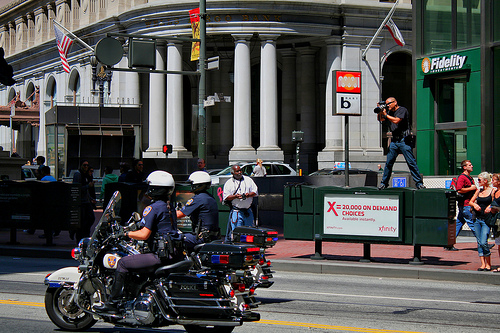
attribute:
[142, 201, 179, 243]
shirt — blue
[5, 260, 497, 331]
road — grey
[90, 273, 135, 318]
boots — black 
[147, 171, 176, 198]
helmet — motorcycle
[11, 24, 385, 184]
building — white, green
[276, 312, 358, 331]
yellow — line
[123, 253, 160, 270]
pants — blue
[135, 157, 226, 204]
helmets — white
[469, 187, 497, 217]
tank top — black 